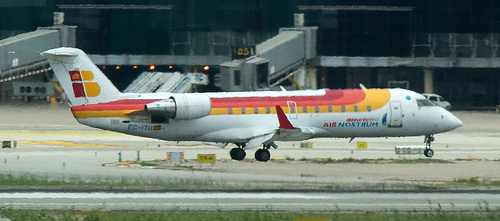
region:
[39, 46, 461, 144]
A white airplane with red and yellow decorations.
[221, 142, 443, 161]
The wheels of the airplane.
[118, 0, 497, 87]
A grey part of the area.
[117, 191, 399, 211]
The road area near the airplane.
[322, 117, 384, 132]
The company name of the airplane.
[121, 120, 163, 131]
The license plate area of the airplane.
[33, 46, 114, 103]
The tail of the airplane.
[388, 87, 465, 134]
The windows and nose of the airplane.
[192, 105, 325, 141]
The wing of the airplane.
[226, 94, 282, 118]
The red and yellow decoration on the airplane.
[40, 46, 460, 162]
white, red, and yellow airplane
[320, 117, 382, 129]
red and blue letters readng "air nostrum"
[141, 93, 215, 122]
white airplane engine oriented to move the plane to the right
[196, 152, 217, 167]
yellow sign with black lettering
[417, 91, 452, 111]
white car with dark windows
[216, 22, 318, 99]
tunnel to allow passengers to board plane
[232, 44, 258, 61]
sign with yellow lettering reading "05"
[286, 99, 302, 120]
emergency door to a plane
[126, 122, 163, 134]
blue letters on a white background reading "EC-ITU"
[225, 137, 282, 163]
wheels on the undercarriage of a white plane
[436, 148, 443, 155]
part of a wheel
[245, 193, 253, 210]
edge of a road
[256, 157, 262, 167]
part of a wheel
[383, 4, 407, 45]
part of a house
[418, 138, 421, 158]
edge of a wheel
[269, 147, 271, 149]
side of a plane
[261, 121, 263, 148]
edge of an ear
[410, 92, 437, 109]
window of a plane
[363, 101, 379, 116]
window of a plane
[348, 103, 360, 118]
window of a plane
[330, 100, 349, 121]
window of a plane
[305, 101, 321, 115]
window of a plane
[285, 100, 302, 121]
window of a plane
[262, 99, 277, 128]
window of a plane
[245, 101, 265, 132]
window of a plane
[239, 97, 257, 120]
window of a plane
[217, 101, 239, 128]
window of a plane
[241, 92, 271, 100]
Red stripe near top of plane.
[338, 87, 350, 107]
Orange stripe on side of plane.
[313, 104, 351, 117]
Yellow stripe on side of plane.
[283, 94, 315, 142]
Door on side of plane.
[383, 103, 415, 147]
Door on side of plane.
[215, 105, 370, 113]
Windows lining side of plane.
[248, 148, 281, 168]
Black wheels on bottom of plane.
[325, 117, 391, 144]
Red and blue letters on side of plane.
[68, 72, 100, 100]
Red and yellow markings on tail of plane.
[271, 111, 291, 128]
Tip of wing is red.